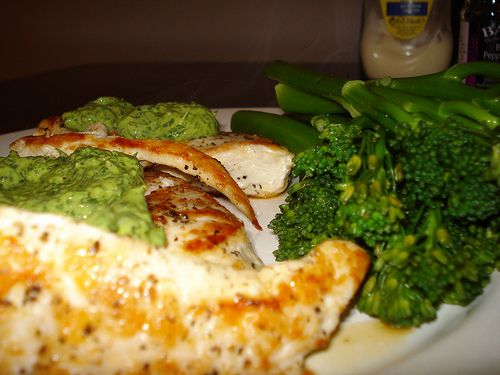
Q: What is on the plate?
A: Food.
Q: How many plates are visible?
A: One.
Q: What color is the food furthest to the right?
A: Green.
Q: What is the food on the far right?
A: Broccoli.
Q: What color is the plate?
A: White.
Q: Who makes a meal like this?
A: Chef.